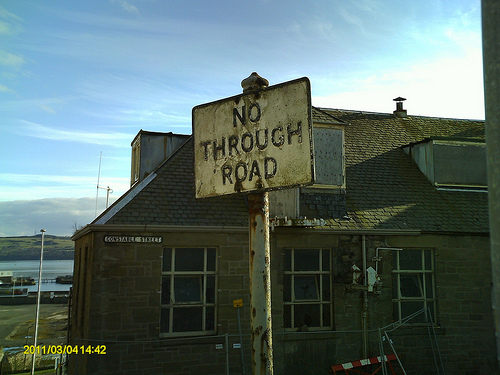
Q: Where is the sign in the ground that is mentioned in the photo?
A: On a old metal pole.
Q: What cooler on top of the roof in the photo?
A: Cooler near tall pole.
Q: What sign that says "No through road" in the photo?
A: White and black sign.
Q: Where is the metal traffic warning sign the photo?
A: Near the building.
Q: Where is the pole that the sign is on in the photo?
A: Front of building.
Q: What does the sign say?
A: No Through Road.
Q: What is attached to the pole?
A: A sign.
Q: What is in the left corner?
A: A date.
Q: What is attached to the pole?
A: A sign.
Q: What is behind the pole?
A: A building.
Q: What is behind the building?
A: A mountain.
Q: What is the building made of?
A: Stone.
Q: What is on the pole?
A: A white sign.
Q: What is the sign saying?
A: No Through Road.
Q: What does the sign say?
A: No Through Road.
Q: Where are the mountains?
A: Behind the building.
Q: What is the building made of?
A: Bricks.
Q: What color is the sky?
A: Blue.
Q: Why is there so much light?
A: It is daytime.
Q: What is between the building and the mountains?
A: Water.